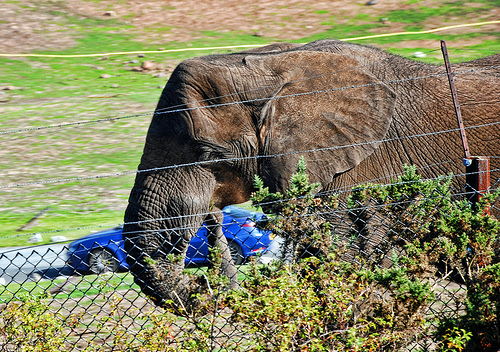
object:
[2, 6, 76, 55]
patch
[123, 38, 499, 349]
elephant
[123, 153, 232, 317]
wrinkled trunk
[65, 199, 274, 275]
car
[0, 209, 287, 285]
road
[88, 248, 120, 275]
black tires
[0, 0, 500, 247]
field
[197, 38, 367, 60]
short hair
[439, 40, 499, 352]
pole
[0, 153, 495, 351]
bush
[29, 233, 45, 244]
rocks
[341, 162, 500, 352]
plate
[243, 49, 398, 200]
left ear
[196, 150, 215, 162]
eye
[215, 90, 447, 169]
left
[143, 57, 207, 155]
forehead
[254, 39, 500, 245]
body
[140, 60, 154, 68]
rocks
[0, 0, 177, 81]
hill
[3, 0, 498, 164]
background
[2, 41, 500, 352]
chain link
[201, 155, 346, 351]
plant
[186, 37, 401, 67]
back hair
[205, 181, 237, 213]
mouth